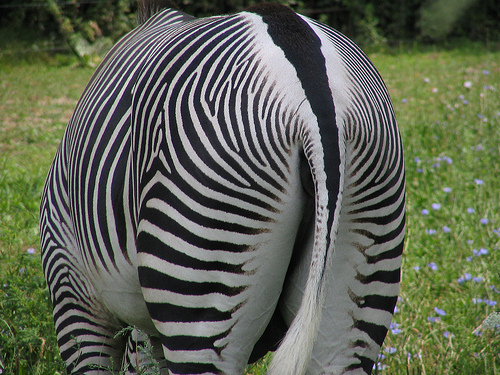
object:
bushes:
[292, 0, 500, 55]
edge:
[266, 279, 327, 373]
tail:
[266, 119, 346, 374]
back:
[152, 320, 269, 375]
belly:
[79, 257, 160, 338]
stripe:
[244, 2, 341, 280]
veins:
[217, 293, 280, 354]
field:
[396, 76, 483, 224]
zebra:
[38, 0, 407, 373]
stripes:
[91, 47, 201, 167]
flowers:
[388, 68, 495, 373]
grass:
[0, 46, 499, 375]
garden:
[0, 0, 499, 375]